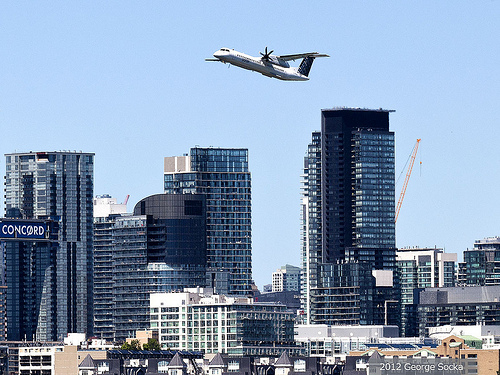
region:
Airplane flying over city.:
[201, 35, 335, 90]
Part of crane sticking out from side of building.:
[397, 115, 430, 232]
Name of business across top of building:
[0, 214, 55, 242]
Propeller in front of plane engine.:
[257, 45, 279, 64]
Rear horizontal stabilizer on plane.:
[308, 48, 337, 64]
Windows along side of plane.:
[234, 51, 260, 66]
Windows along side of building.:
[359, 133, 401, 247]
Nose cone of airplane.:
[211, 50, 228, 60]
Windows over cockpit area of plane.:
[214, 44, 237, 56]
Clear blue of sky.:
[46, 34, 173, 96]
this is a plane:
[183, 0, 340, 96]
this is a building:
[147, 268, 301, 359]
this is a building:
[298, 98, 406, 342]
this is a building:
[392, 248, 461, 322]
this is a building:
[464, 235, 494, 282]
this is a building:
[129, 178, 219, 370]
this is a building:
[0, 144, 117, 364]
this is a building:
[94, 193, 160, 354]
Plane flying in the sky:
[201, 42, 333, 82]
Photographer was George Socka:
[372, 360, 472, 373]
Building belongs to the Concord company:
[1, 221, 50, 240]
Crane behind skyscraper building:
[395, 129, 426, 224]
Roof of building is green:
[448, 333, 485, 348]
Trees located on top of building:
[115, 339, 170, 351]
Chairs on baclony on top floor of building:
[138, 222, 145, 228]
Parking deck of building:
[10, 347, 55, 373]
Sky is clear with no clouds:
[1, 0, 498, 250]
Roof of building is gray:
[409, 287, 499, 303]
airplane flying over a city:
[210, 45, 324, 85]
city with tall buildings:
[6, 106, 498, 369]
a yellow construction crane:
[397, 134, 423, 219]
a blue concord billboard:
[2, 221, 48, 238]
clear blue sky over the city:
[0, 1, 498, 286]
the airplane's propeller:
[259, 50, 272, 62]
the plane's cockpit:
[218, 47, 228, 52]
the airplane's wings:
[205, 53, 317, 61]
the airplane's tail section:
[295, 52, 328, 80]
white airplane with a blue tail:
[202, 47, 327, 87]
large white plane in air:
[210, 40, 332, 90]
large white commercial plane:
[203, 37, 325, 89]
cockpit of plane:
[212, 43, 232, 59]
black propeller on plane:
[255, 45, 280, 65]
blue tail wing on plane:
[295, 49, 324, 73]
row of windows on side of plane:
[235, 55, 261, 65]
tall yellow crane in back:
[395, 140, 430, 206]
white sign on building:
[0, 222, 52, 237]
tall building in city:
[305, 105, 400, 305]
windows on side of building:
[200, 149, 249, 271]